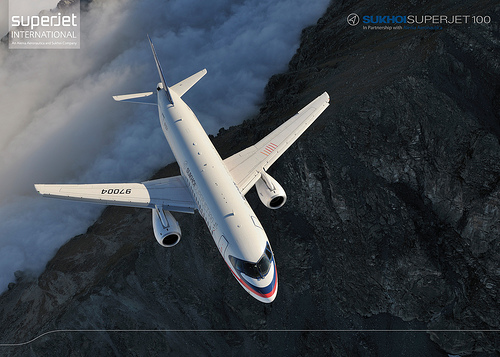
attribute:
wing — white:
[36, 172, 199, 212]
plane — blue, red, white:
[15, 38, 331, 310]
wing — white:
[216, 87, 337, 197]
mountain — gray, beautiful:
[311, 71, 483, 251]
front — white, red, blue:
[231, 256, 278, 298]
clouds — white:
[16, 90, 111, 165]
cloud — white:
[0, 0, 336, 290]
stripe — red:
[266, 143, 276, 152]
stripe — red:
[264, 144, 275, 152]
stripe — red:
[263, 145, 273, 154]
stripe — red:
[258, 149, 269, 156]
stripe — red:
[264, 145, 276, 155]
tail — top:
[110, 36, 211, 108]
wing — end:
[93, 54, 155, 112]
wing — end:
[166, 63, 230, 102]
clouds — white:
[0, 4, 319, 287]